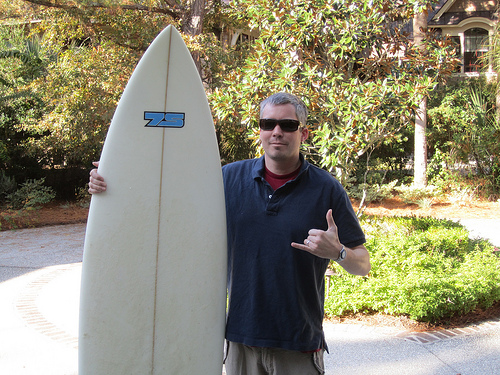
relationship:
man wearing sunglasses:
[87, 91, 372, 374] [258, 118, 302, 134]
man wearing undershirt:
[87, 91, 372, 374] [262, 161, 303, 191]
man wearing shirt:
[87, 91, 372, 374] [222, 152, 366, 355]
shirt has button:
[222, 152, 366, 355] [268, 193, 272, 200]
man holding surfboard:
[87, 91, 372, 374] [80, 23, 227, 374]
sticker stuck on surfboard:
[143, 112, 186, 127] [80, 23, 227, 374]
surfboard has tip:
[80, 23, 227, 374] [164, 24, 181, 34]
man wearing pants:
[87, 91, 372, 374] [223, 337, 325, 375]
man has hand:
[87, 91, 372, 374] [88, 160, 107, 195]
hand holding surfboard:
[88, 160, 107, 195] [80, 23, 227, 374]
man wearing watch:
[87, 91, 372, 374] [334, 245, 349, 265]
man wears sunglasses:
[87, 91, 372, 374] [258, 118, 302, 134]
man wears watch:
[87, 91, 372, 374] [334, 245, 349, 265]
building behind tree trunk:
[367, 0, 499, 174] [413, 4, 428, 189]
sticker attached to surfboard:
[143, 112, 186, 127] [80, 23, 227, 374]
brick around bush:
[413, 331, 439, 342] [324, 214, 499, 323]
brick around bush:
[437, 327, 459, 340] [324, 214, 499, 323]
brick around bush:
[468, 323, 482, 334] [324, 214, 499, 323]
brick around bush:
[446, 326, 464, 336] [324, 214, 499, 323]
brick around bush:
[424, 329, 452, 342] [324, 214, 499, 323]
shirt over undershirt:
[222, 152, 366, 355] [262, 161, 303, 191]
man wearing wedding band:
[87, 91, 372, 374] [306, 240, 311, 246]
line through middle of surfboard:
[149, 23, 174, 375] [80, 23, 227, 374]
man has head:
[87, 91, 372, 374] [258, 94, 310, 161]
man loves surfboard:
[87, 91, 372, 374] [80, 23, 227, 374]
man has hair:
[87, 91, 372, 374] [258, 91, 310, 130]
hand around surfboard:
[88, 160, 107, 195] [80, 23, 227, 374]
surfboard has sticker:
[80, 23, 227, 374] [143, 112, 186, 127]